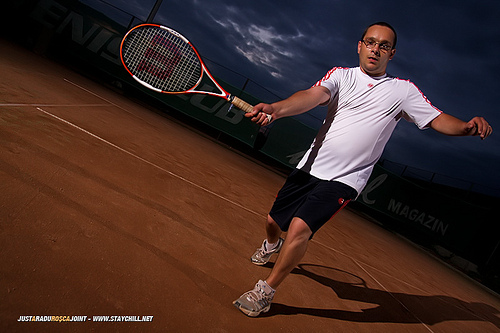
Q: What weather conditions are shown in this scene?
A: It is cloudy.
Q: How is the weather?
A: It is cloudy.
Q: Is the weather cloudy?
A: Yes, it is cloudy.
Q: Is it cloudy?
A: Yes, it is cloudy.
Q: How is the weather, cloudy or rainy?
A: It is cloudy.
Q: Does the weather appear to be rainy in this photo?
A: No, it is cloudy.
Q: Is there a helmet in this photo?
A: No, there are no helmets.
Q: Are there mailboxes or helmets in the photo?
A: No, there are no helmets or mailboxes.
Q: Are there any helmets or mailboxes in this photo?
A: No, there are no helmets or mailboxes.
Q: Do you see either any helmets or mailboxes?
A: No, there are no helmets or mailboxes.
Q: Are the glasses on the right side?
A: Yes, the glasses are on the right of the image.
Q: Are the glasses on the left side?
A: No, the glasses are on the right of the image.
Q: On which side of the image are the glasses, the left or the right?
A: The glasses are on the right of the image.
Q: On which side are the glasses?
A: The glasses are on the right of the image.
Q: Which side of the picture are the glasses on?
A: The glasses are on the right of the image.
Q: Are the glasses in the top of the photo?
A: Yes, the glasses are in the top of the image.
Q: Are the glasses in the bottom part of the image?
A: No, the glasses are in the top of the image.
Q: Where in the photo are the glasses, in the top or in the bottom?
A: The glasses are in the top of the image.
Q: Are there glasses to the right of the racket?
A: Yes, there are glasses to the right of the racket.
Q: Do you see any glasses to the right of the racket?
A: Yes, there are glasses to the right of the racket.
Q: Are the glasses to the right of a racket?
A: Yes, the glasses are to the right of a racket.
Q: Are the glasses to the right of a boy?
A: No, the glasses are to the right of a racket.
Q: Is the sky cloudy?
A: Yes, the sky is cloudy.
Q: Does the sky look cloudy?
A: Yes, the sky is cloudy.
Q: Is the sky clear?
A: No, the sky is cloudy.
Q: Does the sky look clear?
A: No, the sky is cloudy.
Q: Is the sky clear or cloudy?
A: The sky is cloudy.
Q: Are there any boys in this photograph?
A: No, there are no boys.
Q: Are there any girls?
A: No, there are no girls.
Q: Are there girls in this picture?
A: No, there are no girls.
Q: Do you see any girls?
A: No, there are no girls.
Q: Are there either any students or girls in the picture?
A: No, there are no girls or students.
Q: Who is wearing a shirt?
A: The man is wearing a shirt.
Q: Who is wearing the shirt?
A: The man is wearing a shirt.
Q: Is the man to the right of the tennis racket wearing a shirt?
A: Yes, the man is wearing a shirt.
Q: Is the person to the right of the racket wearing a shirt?
A: Yes, the man is wearing a shirt.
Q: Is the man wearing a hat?
A: No, the man is wearing a shirt.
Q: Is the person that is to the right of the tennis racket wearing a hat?
A: No, the man is wearing a shirt.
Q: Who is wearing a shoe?
A: The man is wearing a shoe.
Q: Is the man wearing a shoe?
A: Yes, the man is wearing a shoe.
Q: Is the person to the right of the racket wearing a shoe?
A: Yes, the man is wearing a shoe.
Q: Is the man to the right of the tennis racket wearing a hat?
A: No, the man is wearing a shoe.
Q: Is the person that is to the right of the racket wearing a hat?
A: No, the man is wearing a shoe.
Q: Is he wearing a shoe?
A: Yes, the man is wearing a shoe.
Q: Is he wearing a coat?
A: No, the man is wearing a shoe.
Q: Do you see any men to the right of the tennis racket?
A: Yes, there is a man to the right of the tennis racket.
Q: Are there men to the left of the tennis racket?
A: No, the man is to the right of the tennis racket.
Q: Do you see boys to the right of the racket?
A: No, there is a man to the right of the racket.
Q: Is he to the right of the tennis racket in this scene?
A: Yes, the man is to the right of the tennis racket.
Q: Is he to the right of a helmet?
A: No, the man is to the right of the tennis racket.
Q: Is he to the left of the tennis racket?
A: No, the man is to the right of the tennis racket.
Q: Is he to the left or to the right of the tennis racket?
A: The man is to the right of the tennis racket.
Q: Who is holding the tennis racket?
A: The man is holding the tennis racket.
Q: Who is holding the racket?
A: The man is holding the tennis racket.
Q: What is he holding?
A: The man is holding the tennis racket.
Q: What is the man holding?
A: The man is holding the tennis racket.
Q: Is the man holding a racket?
A: Yes, the man is holding a racket.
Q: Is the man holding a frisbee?
A: No, the man is holding a racket.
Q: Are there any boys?
A: No, there are no boys.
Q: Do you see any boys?
A: No, there are no boys.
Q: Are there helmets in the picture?
A: No, there are no helmets.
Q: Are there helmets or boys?
A: No, there are no helmets or boys.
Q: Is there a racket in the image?
A: Yes, there is a racket.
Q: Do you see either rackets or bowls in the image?
A: Yes, there is a racket.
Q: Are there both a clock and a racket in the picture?
A: No, there is a racket but no clocks.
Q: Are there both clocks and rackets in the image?
A: No, there is a racket but no clocks.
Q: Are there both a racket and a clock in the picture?
A: No, there is a racket but no clocks.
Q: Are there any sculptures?
A: No, there are no sculptures.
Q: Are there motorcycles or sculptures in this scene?
A: No, there are no sculptures or motorcycles.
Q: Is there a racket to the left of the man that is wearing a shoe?
A: Yes, there is a racket to the left of the man.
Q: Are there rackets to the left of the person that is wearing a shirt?
A: Yes, there is a racket to the left of the man.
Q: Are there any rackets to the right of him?
A: No, the racket is to the left of the man.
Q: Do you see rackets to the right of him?
A: No, the racket is to the left of the man.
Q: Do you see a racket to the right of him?
A: No, the racket is to the left of the man.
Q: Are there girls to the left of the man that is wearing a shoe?
A: No, there is a racket to the left of the man.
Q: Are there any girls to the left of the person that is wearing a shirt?
A: No, there is a racket to the left of the man.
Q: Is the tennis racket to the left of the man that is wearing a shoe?
A: Yes, the tennis racket is to the left of the man.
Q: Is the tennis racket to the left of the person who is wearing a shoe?
A: Yes, the tennis racket is to the left of the man.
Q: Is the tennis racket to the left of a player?
A: No, the tennis racket is to the left of the man.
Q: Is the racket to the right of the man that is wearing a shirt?
A: No, the racket is to the left of the man.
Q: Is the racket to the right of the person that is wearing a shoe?
A: No, the racket is to the left of the man.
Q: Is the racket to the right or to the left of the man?
A: The racket is to the left of the man.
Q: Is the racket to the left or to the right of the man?
A: The racket is to the left of the man.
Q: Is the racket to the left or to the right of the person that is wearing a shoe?
A: The racket is to the left of the man.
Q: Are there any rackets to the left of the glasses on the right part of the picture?
A: Yes, there is a racket to the left of the glasses.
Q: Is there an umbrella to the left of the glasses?
A: No, there is a racket to the left of the glasses.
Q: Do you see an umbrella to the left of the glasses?
A: No, there is a racket to the left of the glasses.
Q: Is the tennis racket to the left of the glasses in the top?
A: Yes, the tennis racket is to the left of the glasses.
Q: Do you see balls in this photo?
A: No, there are no balls.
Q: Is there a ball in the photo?
A: No, there are no balls.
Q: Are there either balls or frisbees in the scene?
A: No, there are no balls or frisbees.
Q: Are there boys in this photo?
A: No, there are no boys.